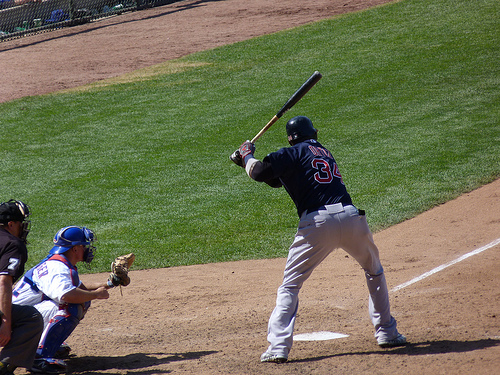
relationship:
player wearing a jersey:
[228, 116, 406, 364] [260, 136, 353, 218]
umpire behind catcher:
[2, 192, 44, 367] [19, 212, 135, 354]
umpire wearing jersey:
[0, 199, 43, 374] [260, 136, 353, 218]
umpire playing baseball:
[0, 199, 43, 374] [3, 3, 496, 371]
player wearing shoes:
[228, 116, 406, 364] [247, 320, 432, 362]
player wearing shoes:
[228, 116, 406, 364] [246, 321, 438, 372]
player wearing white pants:
[228, 116, 406, 364] [232, 183, 433, 373]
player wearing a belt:
[228, 116, 406, 364] [295, 193, 362, 215]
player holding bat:
[228, 116, 406, 364] [269, 77, 327, 123]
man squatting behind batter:
[11, 226, 127, 367] [247, 117, 406, 353]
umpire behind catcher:
[0, 199, 43, 374] [24, 209, 120, 364]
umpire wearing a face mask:
[0, 199, 43, 374] [17, 208, 32, 238]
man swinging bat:
[40, 215, 106, 300] [231, 69, 322, 162]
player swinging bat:
[228, 116, 406, 364] [231, 69, 322, 162]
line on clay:
[418, 246, 492, 274] [459, 291, 483, 333]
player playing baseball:
[228, 116, 406, 364] [5, 65, 485, 365]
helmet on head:
[277, 104, 327, 140] [284, 113, 320, 148]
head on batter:
[284, 113, 320, 148] [234, 65, 410, 367]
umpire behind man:
[0, 199, 43, 374] [11, 226, 127, 367]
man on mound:
[11, 226, 127, 367] [5, 254, 485, 367]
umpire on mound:
[0, 199, 43, 374] [5, 254, 485, 367]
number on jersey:
[298, 137, 355, 198] [260, 136, 353, 218]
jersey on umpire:
[260, 136, 353, 218] [0, 199, 43, 374]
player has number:
[228, 68, 409, 364] [306, 143, 346, 194]